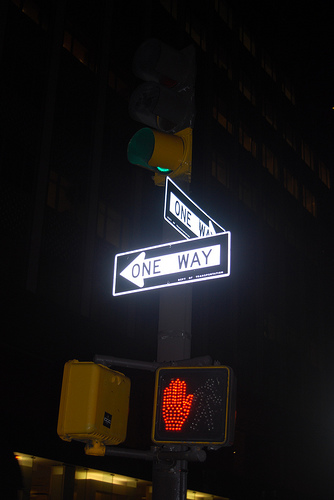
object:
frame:
[6, 445, 272, 497]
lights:
[11, 452, 154, 500]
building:
[0, 0, 333, 500]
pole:
[152, 81, 192, 500]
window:
[214, 108, 233, 137]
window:
[239, 80, 252, 104]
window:
[261, 141, 274, 177]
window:
[287, 138, 296, 152]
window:
[303, 141, 318, 172]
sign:
[153, 367, 228, 443]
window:
[9, 452, 65, 500]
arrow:
[119, 243, 221, 289]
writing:
[177, 271, 223, 282]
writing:
[167, 215, 191, 238]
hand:
[162, 376, 193, 431]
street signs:
[111, 231, 232, 297]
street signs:
[163, 174, 226, 239]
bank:
[201, 9, 333, 203]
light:
[127, 126, 193, 187]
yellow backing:
[155, 127, 193, 185]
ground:
[205, 0, 334, 194]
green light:
[157, 166, 170, 173]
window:
[239, 127, 258, 160]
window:
[285, 162, 294, 197]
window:
[304, 184, 317, 222]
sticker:
[103, 412, 112, 429]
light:
[56, 359, 131, 447]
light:
[151, 366, 236, 451]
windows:
[212, 152, 231, 188]